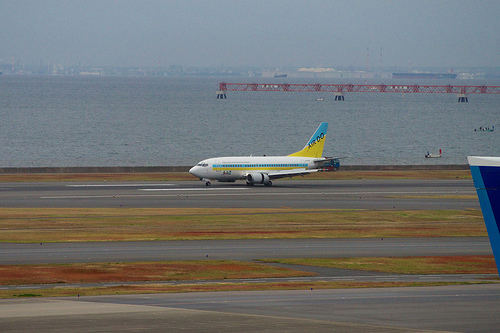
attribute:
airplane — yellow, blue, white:
[162, 116, 376, 210]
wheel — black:
[260, 167, 282, 196]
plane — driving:
[147, 108, 356, 209]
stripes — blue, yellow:
[202, 146, 332, 188]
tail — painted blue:
[296, 113, 348, 153]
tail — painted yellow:
[282, 127, 336, 174]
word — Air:
[300, 127, 349, 160]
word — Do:
[298, 117, 343, 145]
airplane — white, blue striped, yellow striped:
[141, 117, 381, 209]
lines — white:
[66, 180, 244, 191]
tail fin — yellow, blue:
[287, 121, 328, 156]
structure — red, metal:
[215, 79, 497, 101]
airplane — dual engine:
[189, 120, 349, 188]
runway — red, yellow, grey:
[1, 166, 499, 331]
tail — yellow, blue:
[292, 122, 345, 172]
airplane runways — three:
[4, 165, 497, 330]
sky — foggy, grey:
[1, 0, 497, 60]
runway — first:
[2, 275, 498, 331]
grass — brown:
[1, 205, 486, 244]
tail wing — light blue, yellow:
[306, 120, 348, 171]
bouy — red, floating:
[422, 149, 442, 157]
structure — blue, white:
[213, 82, 498, 100]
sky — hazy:
[91, 25, 278, 57]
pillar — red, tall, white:
[357, 40, 379, 68]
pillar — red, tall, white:
[360, 46, 381, 68]